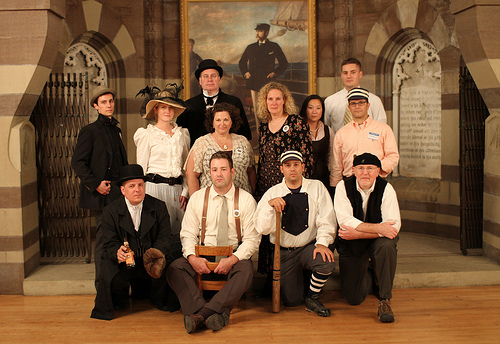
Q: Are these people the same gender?
A: No, they are both male and female.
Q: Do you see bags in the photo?
A: No, there are no bags.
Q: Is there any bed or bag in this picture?
A: No, there are no bags or beds.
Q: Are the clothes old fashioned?
A: Yes, the clothes are old fashioned.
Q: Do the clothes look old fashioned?
A: Yes, the clothes are old fashioned.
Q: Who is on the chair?
A: The man is on the chair.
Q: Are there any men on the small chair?
A: Yes, there is a man on the chair.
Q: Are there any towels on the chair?
A: No, there is a man on the chair.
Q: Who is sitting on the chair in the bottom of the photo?
A: The man is sitting on the chair.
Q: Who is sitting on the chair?
A: The man is sitting on the chair.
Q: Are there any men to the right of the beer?
A: Yes, there is a man to the right of the beer.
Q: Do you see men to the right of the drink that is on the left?
A: Yes, there is a man to the right of the beer.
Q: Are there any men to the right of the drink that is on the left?
A: Yes, there is a man to the right of the beer.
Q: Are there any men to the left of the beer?
A: No, the man is to the right of the beer.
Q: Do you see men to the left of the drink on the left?
A: No, the man is to the right of the beer.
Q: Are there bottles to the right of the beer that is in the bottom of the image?
A: No, there is a man to the right of the beer.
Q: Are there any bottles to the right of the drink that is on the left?
A: No, there is a man to the right of the beer.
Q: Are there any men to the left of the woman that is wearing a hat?
A: No, the man is to the right of the woman.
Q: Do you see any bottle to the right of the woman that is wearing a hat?
A: No, there is a man to the right of the woman.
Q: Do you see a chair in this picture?
A: Yes, there is a chair.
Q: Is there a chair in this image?
A: Yes, there is a chair.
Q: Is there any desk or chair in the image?
A: Yes, there is a chair.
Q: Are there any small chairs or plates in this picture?
A: Yes, there is a small chair.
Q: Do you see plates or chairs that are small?
A: Yes, the chair is small.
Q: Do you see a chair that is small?
A: Yes, there is a small chair.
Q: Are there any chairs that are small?
A: Yes, there is a chair that is small.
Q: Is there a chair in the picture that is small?
A: Yes, there is a chair that is small.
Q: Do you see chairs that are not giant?
A: Yes, there is a small chair.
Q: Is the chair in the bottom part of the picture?
A: Yes, the chair is in the bottom of the image.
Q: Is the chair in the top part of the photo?
A: No, the chair is in the bottom of the image.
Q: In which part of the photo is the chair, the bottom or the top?
A: The chair is in the bottom of the image.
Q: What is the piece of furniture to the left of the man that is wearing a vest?
A: The piece of furniture is a chair.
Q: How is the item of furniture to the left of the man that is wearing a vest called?
A: The piece of furniture is a chair.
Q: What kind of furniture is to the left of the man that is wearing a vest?
A: The piece of furniture is a chair.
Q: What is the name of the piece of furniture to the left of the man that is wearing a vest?
A: The piece of furniture is a chair.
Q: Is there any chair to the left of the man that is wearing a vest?
A: Yes, there is a chair to the left of the man.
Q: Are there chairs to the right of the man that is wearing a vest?
A: No, the chair is to the left of the man.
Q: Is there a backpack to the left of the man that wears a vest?
A: No, there is a chair to the left of the man.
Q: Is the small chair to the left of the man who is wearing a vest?
A: Yes, the chair is to the left of the man.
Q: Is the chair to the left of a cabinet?
A: No, the chair is to the left of the man.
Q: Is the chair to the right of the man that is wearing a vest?
A: No, the chair is to the left of the man.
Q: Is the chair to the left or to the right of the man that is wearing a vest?
A: The chair is to the left of the man.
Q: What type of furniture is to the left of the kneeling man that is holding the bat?
A: The piece of furniture is a chair.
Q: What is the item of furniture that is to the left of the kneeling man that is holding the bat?
A: The piece of furniture is a chair.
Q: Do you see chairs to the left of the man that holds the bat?
A: Yes, there is a chair to the left of the man.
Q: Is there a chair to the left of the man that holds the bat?
A: Yes, there is a chair to the left of the man.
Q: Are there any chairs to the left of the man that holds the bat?
A: Yes, there is a chair to the left of the man.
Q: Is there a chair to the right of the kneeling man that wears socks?
A: No, the chair is to the left of the man.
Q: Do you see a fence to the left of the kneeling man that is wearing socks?
A: No, there is a chair to the left of the man.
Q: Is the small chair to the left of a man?
A: Yes, the chair is to the left of a man.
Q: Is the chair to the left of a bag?
A: No, the chair is to the left of a man.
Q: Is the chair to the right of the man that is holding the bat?
A: No, the chair is to the left of the man.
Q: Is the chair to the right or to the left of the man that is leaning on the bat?
A: The chair is to the left of the man.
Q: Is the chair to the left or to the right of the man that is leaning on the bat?
A: The chair is to the left of the man.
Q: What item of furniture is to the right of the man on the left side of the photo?
A: The piece of furniture is a chair.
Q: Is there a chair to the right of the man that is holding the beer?
A: Yes, there is a chair to the right of the man.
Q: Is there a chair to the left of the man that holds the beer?
A: No, the chair is to the right of the man.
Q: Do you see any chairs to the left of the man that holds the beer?
A: No, the chair is to the right of the man.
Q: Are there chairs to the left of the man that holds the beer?
A: No, the chair is to the right of the man.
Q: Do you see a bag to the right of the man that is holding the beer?
A: No, there is a chair to the right of the man.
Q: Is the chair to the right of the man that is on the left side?
A: Yes, the chair is to the right of the man.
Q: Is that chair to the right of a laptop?
A: No, the chair is to the right of the man.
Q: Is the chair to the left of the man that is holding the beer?
A: No, the chair is to the right of the man.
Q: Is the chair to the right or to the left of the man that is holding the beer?
A: The chair is to the right of the man.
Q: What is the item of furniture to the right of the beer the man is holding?
A: The piece of furniture is a chair.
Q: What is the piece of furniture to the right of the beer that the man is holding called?
A: The piece of furniture is a chair.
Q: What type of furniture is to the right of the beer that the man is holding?
A: The piece of furniture is a chair.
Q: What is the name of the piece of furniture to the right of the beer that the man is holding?
A: The piece of furniture is a chair.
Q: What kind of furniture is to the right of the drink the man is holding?
A: The piece of furniture is a chair.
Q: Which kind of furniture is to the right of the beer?
A: The piece of furniture is a chair.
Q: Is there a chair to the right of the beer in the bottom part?
A: Yes, there is a chair to the right of the beer.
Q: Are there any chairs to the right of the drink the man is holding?
A: Yes, there is a chair to the right of the beer.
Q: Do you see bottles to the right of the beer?
A: No, there is a chair to the right of the beer.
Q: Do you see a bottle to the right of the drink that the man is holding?
A: No, there is a chair to the right of the beer.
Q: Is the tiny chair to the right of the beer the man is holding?
A: Yes, the chair is to the right of the beer.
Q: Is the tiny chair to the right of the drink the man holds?
A: Yes, the chair is to the right of the beer.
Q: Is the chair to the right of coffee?
A: No, the chair is to the right of the beer.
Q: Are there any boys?
A: No, there are no boys.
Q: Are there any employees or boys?
A: No, there are no boys or employees.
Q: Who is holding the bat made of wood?
A: The man is holding the bat.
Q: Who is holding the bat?
A: The man is holding the bat.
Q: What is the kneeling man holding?
A: The man is holding the bat.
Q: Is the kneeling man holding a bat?
A: Yes, the man is holding a bat.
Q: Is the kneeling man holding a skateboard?
A: No, the man is holding a bat.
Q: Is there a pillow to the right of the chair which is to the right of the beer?
A: No, there is a man to the right of the chair.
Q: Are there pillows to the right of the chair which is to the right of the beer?
A: No, there is a man to the right of the chair.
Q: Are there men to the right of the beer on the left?
A: Yes, there is a man to the right of the beer.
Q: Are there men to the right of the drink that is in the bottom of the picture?
A: Yes, there is a man to the right of the beer.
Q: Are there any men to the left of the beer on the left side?
A: No, the man is to the right of the beer.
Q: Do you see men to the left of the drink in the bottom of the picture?
A: No, the man is to the right of the beer.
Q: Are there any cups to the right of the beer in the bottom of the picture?
A: No, there is a man to the right of the beer.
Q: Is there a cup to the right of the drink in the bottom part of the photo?
A: No, there is a man to the right of the beer.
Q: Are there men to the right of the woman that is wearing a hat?
A: Yes, there is a man to the right of the woman.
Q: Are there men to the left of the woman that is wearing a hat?
A: No, the man is to the right of the woman.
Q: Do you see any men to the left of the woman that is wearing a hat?
A: No, the man is to the right of the woman.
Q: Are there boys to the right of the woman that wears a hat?
A: No, there is a man to the right of the woman.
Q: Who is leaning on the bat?
A: The man is leaning on the bat.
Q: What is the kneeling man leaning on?
A: The man is leaning on the bat.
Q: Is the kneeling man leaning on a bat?
A: Yes, the man is leaning on a bat.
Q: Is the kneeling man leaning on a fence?
A: No, the man is leaning on a bat.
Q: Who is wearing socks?
A: The man is wearing socks.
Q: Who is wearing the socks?
A: The man is wearing socks.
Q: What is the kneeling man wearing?
A: The man is wearing socks.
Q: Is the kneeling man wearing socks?
A: Yes, the man is wearing socks.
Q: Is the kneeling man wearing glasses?
A: No, the man is wearing socks.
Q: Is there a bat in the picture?
A: Yes, there is a bat.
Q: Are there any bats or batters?
A: Yes, there is a bat.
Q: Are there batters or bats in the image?
A: Yes, there is a bat.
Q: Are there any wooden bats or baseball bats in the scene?
A: Yes, there is a wood bat.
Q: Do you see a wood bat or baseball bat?
A: Yes, there is a wood bat.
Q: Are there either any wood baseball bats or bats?
A: Yes, there is a wood bat.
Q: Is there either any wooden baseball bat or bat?
A: Yes, there is a wood bat.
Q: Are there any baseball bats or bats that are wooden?
A: Yes, the bat is wooden.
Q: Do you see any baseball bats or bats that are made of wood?
A: Yes, the bat is made of wood.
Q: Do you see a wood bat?
A: Yes, there is a bat that is made of wood.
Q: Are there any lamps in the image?
A: No, there are no lamps.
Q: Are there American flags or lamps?
A: No, there are no lamps or American flags.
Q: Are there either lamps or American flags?
A: No, there are no lamps or American flags.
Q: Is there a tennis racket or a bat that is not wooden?
A: No, there is a bat but it is wooden.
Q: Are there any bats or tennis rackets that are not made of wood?
A: No, there is a bat but it is made of wood.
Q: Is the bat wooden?
A: Yes, the bat is wooden.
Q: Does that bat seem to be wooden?
A: Yes, the bat is wooden.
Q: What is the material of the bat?
A: The bat is made of wood.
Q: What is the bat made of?
A: The bat is made of wood.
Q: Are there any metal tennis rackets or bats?
A: No, there is a bat but it is wooden.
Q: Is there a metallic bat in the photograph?
A: No, there is a bat but it is wooden.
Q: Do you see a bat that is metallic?
A: No, there is a bat but it is wooden.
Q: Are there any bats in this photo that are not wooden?
A: No, there is a bat but it is wooden.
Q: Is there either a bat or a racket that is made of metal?
A: No, there is a bat but it is made of wood.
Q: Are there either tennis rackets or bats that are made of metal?
A: No, there is a bat but it is made of wood.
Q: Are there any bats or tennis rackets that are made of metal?
A: No, there is a bat but it is made of wood.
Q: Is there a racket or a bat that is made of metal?
A: No, there is a bat but it is made of wood.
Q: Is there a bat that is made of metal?
A: No, there is a bat but it is made of wood.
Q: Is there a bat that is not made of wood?
A: No, there is a bat but it is made of wood.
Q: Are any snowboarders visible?
A: No, there are no snowboarders.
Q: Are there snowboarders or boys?
A: No, there are no snowboarders or boys.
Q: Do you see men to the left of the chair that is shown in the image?
A: Yes, there is a man to the left of the chair.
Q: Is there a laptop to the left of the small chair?
A: No, there is a man to the left of the chair.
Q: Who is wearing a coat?
A: The man is wearing a coat.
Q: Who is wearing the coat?
A: The man is wearing a coat.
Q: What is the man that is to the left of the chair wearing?
A: The man is wearing a coat.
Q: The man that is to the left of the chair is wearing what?
A: The man is wearing a coat.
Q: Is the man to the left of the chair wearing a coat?
A: Yes, the man is wearing a coat.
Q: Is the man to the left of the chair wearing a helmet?
A: No, the man is wearing a coat.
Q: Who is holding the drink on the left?
A: The man is holding the beer.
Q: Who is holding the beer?
A: The man is holding the beer.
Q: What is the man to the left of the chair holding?
A: The man is holding the beer.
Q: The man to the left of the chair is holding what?
A: The man is holding the beer.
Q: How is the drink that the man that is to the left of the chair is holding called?
A: The drink is beer.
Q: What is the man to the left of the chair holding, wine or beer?
A: The man is holding beer.